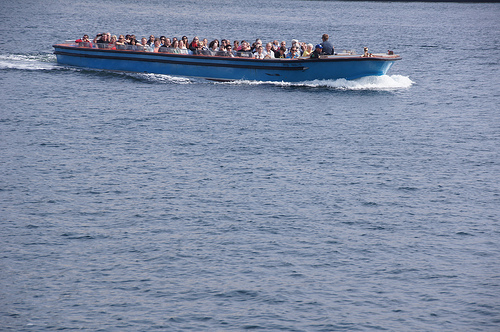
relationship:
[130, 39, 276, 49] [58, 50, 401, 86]
people on boat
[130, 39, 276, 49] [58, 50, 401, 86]
people sitting on boat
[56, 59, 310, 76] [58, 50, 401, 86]
line on side of boat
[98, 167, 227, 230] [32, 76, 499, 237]
ripple in water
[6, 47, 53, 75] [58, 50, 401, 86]
waves behind boat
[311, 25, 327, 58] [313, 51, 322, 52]
person wearing hat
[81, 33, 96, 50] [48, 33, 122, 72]
person on back of boat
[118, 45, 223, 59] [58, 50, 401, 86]
shield on side of boat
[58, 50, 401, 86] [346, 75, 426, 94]
boat on top of water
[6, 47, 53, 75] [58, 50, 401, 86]
waves by boat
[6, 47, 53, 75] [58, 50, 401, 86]
waves coming from boat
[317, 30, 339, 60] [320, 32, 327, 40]
man has head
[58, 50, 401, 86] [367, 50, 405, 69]
boat has bow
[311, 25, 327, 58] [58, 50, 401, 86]
person on boat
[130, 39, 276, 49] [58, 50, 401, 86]
people inside of boat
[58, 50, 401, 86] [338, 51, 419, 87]
boat has front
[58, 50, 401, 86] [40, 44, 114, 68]
boat has back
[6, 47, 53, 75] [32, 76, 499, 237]
waves inside water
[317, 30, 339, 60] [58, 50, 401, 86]
man standing on boat